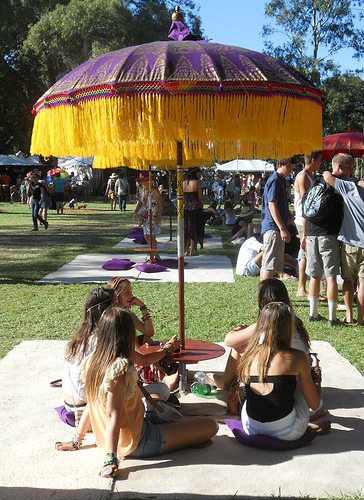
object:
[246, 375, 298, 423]
black top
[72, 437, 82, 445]
bracelets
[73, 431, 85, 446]
wrist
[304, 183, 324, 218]
design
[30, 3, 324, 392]
umbrella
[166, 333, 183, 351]
hand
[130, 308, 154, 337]
arm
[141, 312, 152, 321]
braclets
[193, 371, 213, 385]
bottles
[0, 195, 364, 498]
ground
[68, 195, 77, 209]
child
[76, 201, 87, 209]
dog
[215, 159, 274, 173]
umbrella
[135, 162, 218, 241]
umbrella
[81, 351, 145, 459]
top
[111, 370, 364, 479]
shadow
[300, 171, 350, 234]
shirt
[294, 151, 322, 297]
man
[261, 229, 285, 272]
shorts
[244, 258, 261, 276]
shorts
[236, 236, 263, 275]
shirt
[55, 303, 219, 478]
girl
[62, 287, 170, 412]
girl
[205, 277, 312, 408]
girl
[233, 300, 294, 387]
hair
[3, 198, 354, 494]
grass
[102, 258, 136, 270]
pillow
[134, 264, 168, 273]
pillow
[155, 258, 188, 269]
pillow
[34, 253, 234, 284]
blanket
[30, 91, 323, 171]
fringe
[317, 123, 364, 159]
umbrella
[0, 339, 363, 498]
blanket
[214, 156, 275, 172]
shelter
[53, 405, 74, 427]
pillow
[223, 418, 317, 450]
pillow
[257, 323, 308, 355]
top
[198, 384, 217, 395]
bottles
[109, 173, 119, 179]
hat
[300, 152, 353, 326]
man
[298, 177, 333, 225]
backpack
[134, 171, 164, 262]
woman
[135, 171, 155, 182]
cowboy hat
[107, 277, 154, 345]
woman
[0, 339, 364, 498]
slab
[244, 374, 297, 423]
shirt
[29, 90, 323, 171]
tassels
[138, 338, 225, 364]
table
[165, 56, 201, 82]
designs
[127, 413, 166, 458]
shorts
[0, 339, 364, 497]
pad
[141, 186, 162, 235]
dress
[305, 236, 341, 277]
shorts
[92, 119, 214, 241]
umbrella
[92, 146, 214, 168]
fringes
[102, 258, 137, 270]
cushion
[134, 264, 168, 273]
cushion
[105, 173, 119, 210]
person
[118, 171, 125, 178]
hat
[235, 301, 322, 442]
girl